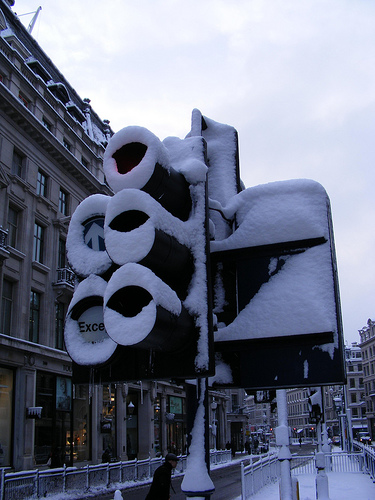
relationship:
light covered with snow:
[97, 100, 327, 386] [79, 130, 332, 368]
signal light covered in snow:
[64, 106, 215, 385] [85, 199, 105, 212]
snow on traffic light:
[252, 182, 313, 235] [61, 105, 349, 397]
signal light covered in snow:
[64, 106, 215, 385] [244, 195, 300, 237]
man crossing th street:
[147, 451, 183, 497] [78, 443, 319, 497]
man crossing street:
[235, 437, 264, 468] [118, 435, 336, 489]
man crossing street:
[146, 453, 181, 499] [78, 443, 319, 497]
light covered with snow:
[97, 100, 327, 386] [58, 84, 350, 391]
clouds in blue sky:
[9, 0, 374, 352] [0, 0, 374, 346]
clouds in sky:
[9, 0, 374, 352] [143, 38, 228, 67]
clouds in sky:
[9, 0, 374, 352] [10, 0, 373, 346]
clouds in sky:
[343, 219, 360, 261] [10, 0, 373, 346]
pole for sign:
[181, 375, 216, 499] [51, 293, 131, 356]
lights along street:
[266, 424, 314, 431] [252, 431, 339, 448]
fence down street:
[0, 446, 236, 497] [78, 443, 319, 497]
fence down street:
[239, 447, 292, 496] [78, 443, 319, 497]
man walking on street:
[146, 453, 181, 499] [78, 443, 319, 497]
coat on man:
[149, 461, 172, 499] [141, 452, 181, 498]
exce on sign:
[75, 315, 107, 334] [212, 176, 347, 391]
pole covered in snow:
[181, 375, 216, 499] [179, 377, 215, 491]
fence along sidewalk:
[0, 447, 232, 497] [3, 435, 242, 496]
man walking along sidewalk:
[146, 453, 181, 499] [9, 464, 188, 498]